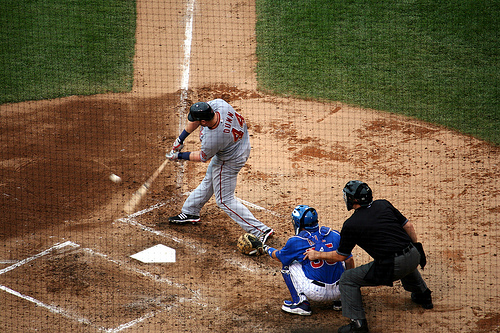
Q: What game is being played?
A: Baseball.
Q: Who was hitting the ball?
A: The hitter.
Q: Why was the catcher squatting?
A: To catch the ball.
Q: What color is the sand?
A: Brown.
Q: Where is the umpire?
A: Standing behind the catcher.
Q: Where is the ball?
A: Going over the plate.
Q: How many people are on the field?
A: Three.